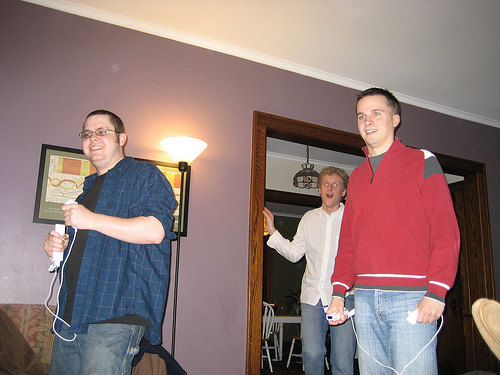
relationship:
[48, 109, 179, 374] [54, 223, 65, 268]
guy holding controller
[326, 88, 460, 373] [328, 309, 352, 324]
guy holding controller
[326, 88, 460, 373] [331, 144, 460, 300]
guy in sweater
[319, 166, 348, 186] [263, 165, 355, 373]
curlie haired man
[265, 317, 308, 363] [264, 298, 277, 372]
table and chairs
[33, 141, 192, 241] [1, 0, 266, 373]
picture on wall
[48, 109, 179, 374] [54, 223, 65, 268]
man holding controller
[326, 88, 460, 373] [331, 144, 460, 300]
man wearing sweater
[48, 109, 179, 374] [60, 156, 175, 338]
guy wearing shirt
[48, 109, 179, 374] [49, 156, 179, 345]
guy wearing shirt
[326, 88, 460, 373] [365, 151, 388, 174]
man wearing shirt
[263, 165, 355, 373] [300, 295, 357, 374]
man wearing pants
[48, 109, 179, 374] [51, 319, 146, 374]
guy wearing pants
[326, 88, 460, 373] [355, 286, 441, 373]
guy wearing pants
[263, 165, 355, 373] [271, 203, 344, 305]
man wearing shirt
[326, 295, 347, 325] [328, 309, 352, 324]
hand holding controller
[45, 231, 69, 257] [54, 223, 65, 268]
hand holding controller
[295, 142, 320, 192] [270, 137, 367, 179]
lamp on ceiling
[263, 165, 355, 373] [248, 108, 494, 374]
man in archway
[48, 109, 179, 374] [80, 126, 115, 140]
guy wearing glasses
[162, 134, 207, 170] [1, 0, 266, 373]
light by wall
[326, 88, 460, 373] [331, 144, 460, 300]
guy wearing sweater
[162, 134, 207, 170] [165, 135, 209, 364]
top of lamp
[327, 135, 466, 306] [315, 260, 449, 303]
shirt with stripes